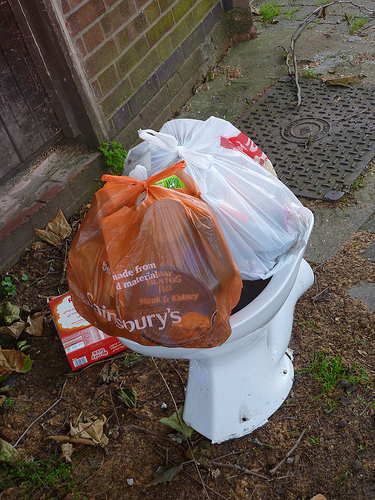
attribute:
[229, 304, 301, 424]
porcelain toilet — broken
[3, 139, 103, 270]
steps — covered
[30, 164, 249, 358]
bag — orange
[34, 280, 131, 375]
box — red, white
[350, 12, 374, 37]
grass — green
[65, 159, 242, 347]
bag — orange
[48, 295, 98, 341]
cardboard box — empty, red, white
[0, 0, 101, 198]
door — brown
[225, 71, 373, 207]
grate — black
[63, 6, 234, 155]
wall — green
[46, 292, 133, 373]
box — red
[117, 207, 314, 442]
toilet — white , bowl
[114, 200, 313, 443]
toilet seat — Toilet 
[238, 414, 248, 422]
screw — black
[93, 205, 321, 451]
toilet — broken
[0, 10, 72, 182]
door — wooden , side